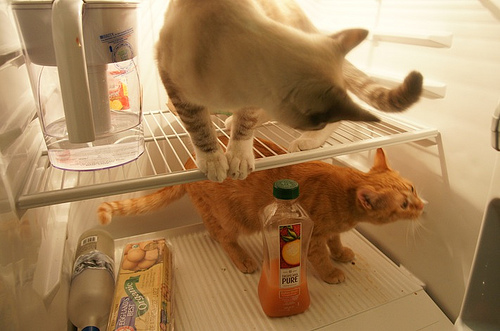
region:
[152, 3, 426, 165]
the cat in fridge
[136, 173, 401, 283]
the cat in the fridge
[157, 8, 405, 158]
the cat on the wire shelf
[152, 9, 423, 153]
the cat is tan with beige stripes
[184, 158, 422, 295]
the cat is auburn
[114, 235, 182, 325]
carton of eggs in the fridge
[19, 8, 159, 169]
pitcher on the shelf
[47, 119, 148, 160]
water in the pitcher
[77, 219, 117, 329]
the bottle in the fridge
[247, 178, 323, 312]
the orange juice in the fridge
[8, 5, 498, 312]
a refrigerator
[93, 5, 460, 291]
two cats in a refrigerator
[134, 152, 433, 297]
an orange cat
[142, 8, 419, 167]
a white and grey cat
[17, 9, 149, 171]
a water pitcher in the fridge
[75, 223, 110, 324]
a bottle laying down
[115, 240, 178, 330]
a carton of eggs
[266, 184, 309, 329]
a bottle of juice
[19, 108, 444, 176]
a shelf in the fridge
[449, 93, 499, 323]
the door of the fridge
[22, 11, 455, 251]
this is in a kitchen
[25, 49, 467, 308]
this is in a fridge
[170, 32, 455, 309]
these are cats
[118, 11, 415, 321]
the cats are playing in the fridge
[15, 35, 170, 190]
this is clean water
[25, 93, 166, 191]
the water pitcher has a filter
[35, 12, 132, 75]
the pitcher is white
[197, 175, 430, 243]
this cat is orange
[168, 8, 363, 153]
this cat is white and gray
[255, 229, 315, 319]
this is fruit juice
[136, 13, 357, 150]
cat on fridge shelf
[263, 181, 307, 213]
green lid on bottle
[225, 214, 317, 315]
orange juice in bottle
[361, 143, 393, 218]
cat has orange ears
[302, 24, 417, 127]
grey and brown tail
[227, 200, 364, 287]
cat has orange paws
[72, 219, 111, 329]
vodka bottle in fridge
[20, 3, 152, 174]
white handle on pitcher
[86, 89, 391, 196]
white shelf on fridge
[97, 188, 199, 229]
orange and white tail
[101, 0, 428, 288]
two cats inside refrigerator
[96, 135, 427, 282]
orange cat inside refrigerator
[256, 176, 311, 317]
bottle of juice in front of cat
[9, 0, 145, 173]
jar of water next to cat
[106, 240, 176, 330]
carton of eggs next to bottle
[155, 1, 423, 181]
white and gray cat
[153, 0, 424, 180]
cat is looking down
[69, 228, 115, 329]
bottle next to egg carton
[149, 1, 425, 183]
cat standing on top rack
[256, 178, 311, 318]
bottle has green cap